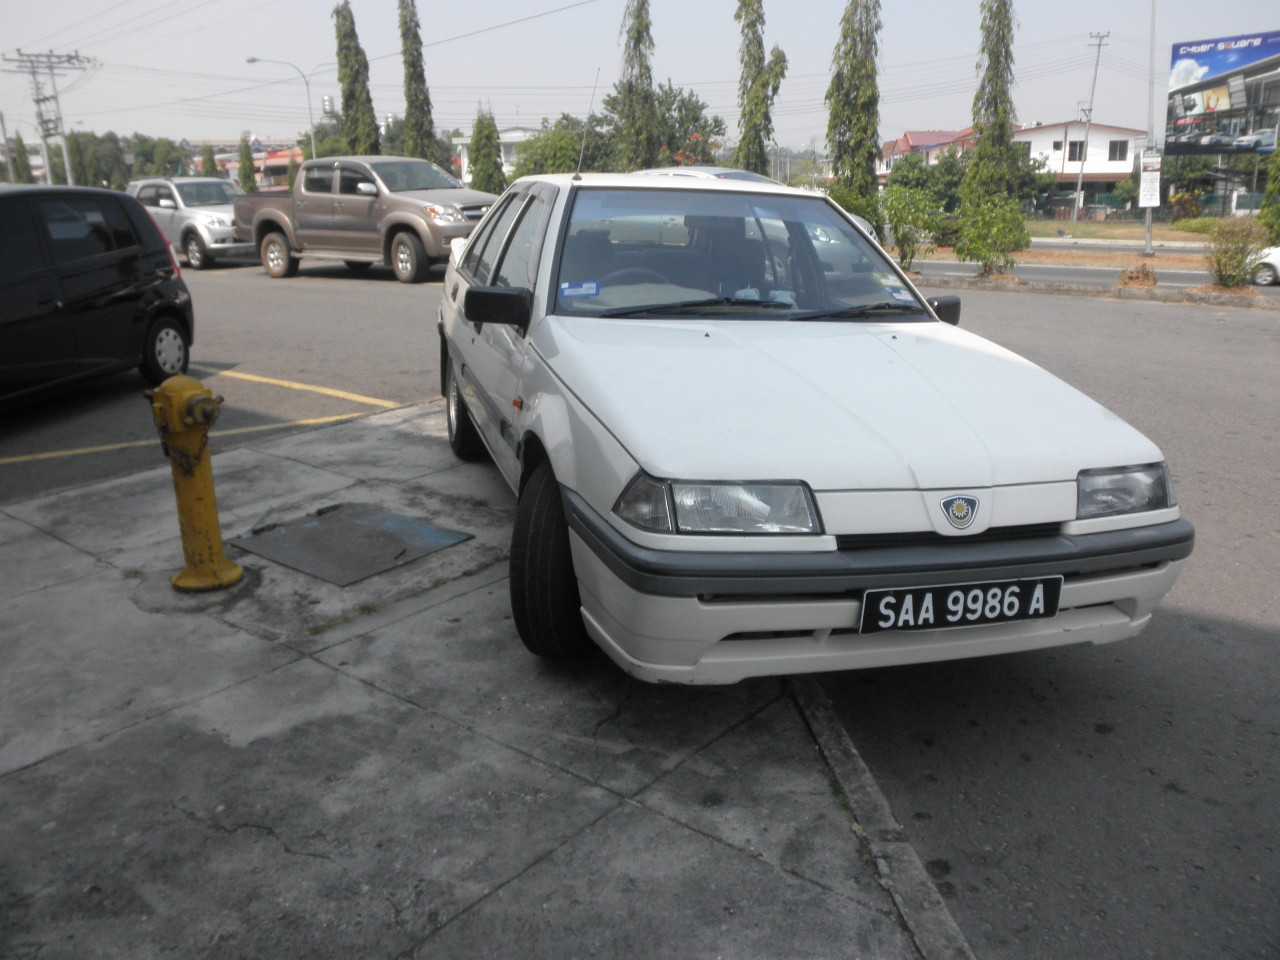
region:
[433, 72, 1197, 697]
the car is white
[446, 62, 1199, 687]
the antenna on the white car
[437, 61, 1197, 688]
the short antenna on the white car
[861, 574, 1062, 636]
the license plate is black and white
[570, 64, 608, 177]
the antenna is short and silver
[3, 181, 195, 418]
the parked car is black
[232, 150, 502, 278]
the truck is gray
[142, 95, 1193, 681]
the white car next to the yellow object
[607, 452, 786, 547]
light on the car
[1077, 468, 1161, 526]
light on the car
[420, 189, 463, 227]
light on the car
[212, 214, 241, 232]
light on the car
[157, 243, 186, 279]
light on the car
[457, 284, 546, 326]
mirror on the car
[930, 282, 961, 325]
mirror on the car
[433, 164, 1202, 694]
White car parked over sidewalk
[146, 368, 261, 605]
Yellow fire hydrant on sidewalk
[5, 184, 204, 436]
Black car parked in parking spot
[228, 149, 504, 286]
Light grey truck driving on road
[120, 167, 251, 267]
Light grey car driving on road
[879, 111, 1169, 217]
White house in background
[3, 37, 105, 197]
Silver pole attached to electrical wires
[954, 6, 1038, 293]
Tall and skinny tree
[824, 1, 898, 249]
Tall and skinny tree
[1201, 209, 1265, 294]
Small bush in middle of road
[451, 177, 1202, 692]
a white car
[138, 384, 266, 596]
a yellow fire hydrant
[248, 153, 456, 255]
a brown truck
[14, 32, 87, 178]
a power pole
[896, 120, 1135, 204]
a white house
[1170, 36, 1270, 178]
a billboard sign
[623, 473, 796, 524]
the headlight on the car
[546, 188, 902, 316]
the windshield on the car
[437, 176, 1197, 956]
car parked on curb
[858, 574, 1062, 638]
black license plate with white characters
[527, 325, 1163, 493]
white hood of car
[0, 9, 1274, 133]
wires suspended in mid air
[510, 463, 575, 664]
tread of rubber tire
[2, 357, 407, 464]
yellow lines on asphalt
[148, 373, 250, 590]
side of yellow fire hydrant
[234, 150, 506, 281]
front side of truck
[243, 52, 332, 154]
light on curved pole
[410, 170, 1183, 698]
a car on a street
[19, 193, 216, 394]
a car on a street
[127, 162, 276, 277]
a car on a street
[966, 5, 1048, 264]
a tree in a city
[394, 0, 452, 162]
a tree in a city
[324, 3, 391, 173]
a tree in a city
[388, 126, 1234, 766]
car on a curb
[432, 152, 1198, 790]
the car is white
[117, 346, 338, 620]
fire hydrant on curb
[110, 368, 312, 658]
the hydrant is yellow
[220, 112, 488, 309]
truck in the background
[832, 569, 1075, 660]
licence plate on the car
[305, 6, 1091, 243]
a row of trees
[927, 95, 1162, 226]
building in the background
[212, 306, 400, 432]
yellow line on the ground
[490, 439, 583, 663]
part of a car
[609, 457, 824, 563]
part of a car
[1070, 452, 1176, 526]
part of a car